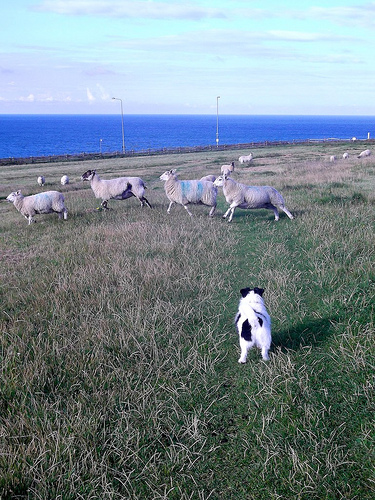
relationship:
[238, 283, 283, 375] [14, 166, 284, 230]
dog for sheep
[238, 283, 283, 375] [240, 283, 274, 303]
dog has ears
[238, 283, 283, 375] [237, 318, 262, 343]
dog has spot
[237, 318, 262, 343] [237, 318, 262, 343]
spot near spot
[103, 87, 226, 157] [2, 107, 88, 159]
streetlights near water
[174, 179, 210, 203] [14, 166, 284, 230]
marks on sheep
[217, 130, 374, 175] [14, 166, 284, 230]
sheep behind sheep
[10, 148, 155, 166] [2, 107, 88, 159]
fence near water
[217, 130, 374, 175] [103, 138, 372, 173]
sheep in distance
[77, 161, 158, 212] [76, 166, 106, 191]
sheep has face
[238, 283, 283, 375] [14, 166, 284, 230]
dog herding sheep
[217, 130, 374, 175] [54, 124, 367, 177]
sheep in background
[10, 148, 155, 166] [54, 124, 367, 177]
fence in background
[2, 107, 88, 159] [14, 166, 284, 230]
water behind sheep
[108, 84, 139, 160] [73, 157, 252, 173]
light behind field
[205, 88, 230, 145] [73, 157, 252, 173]
light behind field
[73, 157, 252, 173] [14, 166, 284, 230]
field of sheep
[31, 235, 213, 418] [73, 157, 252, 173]
grass in field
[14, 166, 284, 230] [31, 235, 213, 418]
sheep in grass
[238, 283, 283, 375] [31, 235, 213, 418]
dog in grass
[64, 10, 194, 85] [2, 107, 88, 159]
clouds over water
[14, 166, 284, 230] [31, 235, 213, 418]
sheep on grass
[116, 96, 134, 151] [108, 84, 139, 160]
post for light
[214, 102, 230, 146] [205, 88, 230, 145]
post for light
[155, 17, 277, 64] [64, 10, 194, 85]
clouds in sky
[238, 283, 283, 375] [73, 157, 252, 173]
dog in field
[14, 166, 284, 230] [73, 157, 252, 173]
sheep in field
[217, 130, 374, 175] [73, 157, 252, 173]
sheep in field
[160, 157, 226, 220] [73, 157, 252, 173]
sheep in field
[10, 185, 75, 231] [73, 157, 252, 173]
sheep in field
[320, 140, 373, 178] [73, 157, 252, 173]
sheep in field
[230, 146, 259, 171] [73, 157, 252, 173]
sheep in field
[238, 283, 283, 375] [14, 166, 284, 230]
collie watching sheep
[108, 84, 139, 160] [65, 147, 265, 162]
light at road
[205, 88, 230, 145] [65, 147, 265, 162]
light at road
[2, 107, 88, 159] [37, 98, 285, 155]
water of ocean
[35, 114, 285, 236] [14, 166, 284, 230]
herd of sheep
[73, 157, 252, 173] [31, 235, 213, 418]
field of grass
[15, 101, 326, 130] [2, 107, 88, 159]
horizon over water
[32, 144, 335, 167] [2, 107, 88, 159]
coast over water